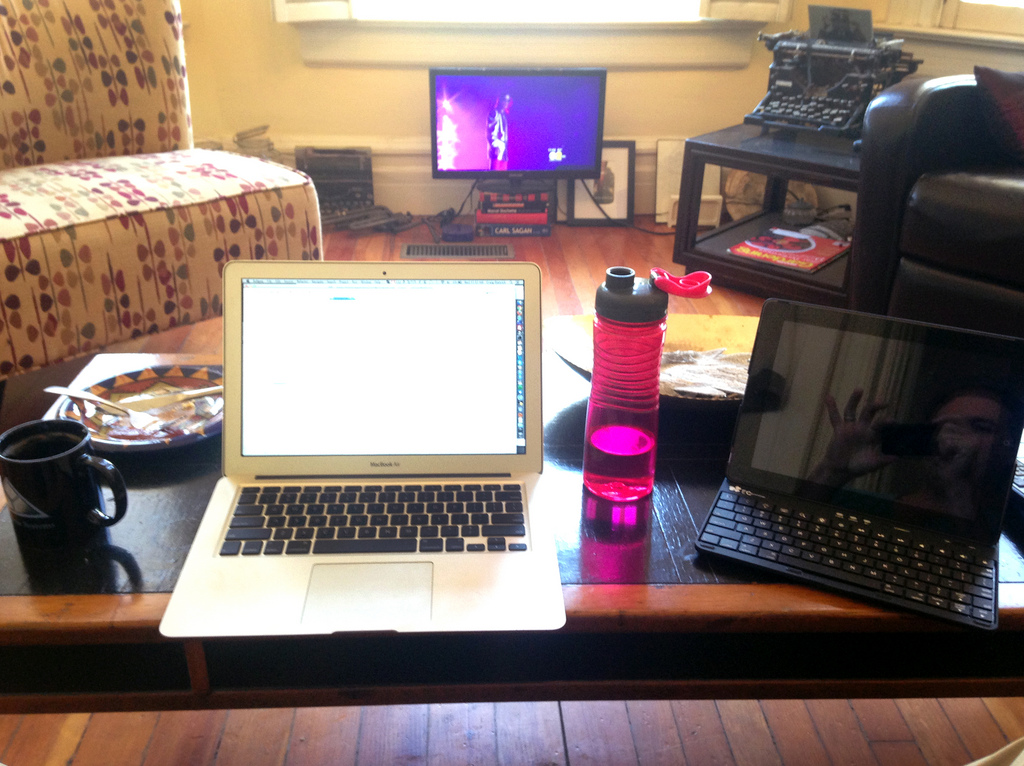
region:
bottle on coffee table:
[570, 252, 720, 544]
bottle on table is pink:
[572, 248, 721, 546]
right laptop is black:
[695, 277, 1022, 655]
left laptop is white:
[158, 242, 579, 650]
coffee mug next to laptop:
[3, 407, 133, 543]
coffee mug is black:
[4, 410, 135, 541]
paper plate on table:
[52, 356, 226, 454]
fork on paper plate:
[48, 375, 191, 445]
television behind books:
[409, 53, 621, 184]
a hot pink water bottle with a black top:
[583, 263, 666, 502]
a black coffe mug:
[2, 416, 127, 541]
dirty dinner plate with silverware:
[42, 363, 227, 461]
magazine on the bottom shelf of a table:
[725, 220, 849, 281]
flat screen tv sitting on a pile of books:
[424, 60, 615, 193]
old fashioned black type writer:
[744, 3, 921, 143]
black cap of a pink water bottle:
[588, 268, 712, 323]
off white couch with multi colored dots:
[2, 6, 323, 370]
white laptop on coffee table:
[0, 257, 1022, 710]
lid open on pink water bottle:
[570, 259, 714, 517]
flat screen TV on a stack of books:
[418, 58, 619, 239]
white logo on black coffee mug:
[1, 412, 137, 561]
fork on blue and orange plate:
[42, 352, 229, 450]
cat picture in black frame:
[562, 134, 635, 224]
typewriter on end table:
[671, 7, 927, 283]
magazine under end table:
[668, 111, 868, 333]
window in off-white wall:
[181, 4, 1022, 226]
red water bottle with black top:
[580, 255, 729, 521]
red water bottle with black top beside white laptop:
[159, 251, 729, 651]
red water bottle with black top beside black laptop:
[579, 252, 1020, 652]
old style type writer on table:
[693, 4, 921, 170]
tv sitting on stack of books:
[422, 62, 610, 241]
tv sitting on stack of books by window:
[422, 2, 615, 231]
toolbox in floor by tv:
[293, 140, 547, 248]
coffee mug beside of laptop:
[13, 252, 563, 632]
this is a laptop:
[120, 180, 719, 706]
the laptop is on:
[151, 219, 682, 647]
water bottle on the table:
[574, 243, 674, 516]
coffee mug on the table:
[0, 410, 130, 548]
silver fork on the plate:
[40, 356, 180, 445]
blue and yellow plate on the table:
[56, 348, 244, 472]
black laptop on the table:
[705, 271, 1007, 654]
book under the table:
[727, 203, 860, 292]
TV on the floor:
[419, 54, 625, 191]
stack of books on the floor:
[471, 186, 561, 240]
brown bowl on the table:
[555, 287, 803, 434]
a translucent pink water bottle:
[580, 265, 667, 506]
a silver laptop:
[158, 258, 570, 641]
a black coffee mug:
[2, 417, 126, 539]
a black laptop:
[697, 294, 1023, 634]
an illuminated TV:
[423, 62, 607, 183]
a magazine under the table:
[724, 214, 843, 278]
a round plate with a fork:
[56, 363, 222, 459]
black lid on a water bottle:
[593, 263, 715, 328]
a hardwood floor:
[319, 203, 766, 322]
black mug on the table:
[5, 414, 139, 554]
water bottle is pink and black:
[588, 230, 687, 529]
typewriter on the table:
[755, 23, 921, 140]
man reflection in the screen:
[824, 358, 1003, 545]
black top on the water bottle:
[596, 259, 669, 326]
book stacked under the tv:
[458, 174, 564, 245]